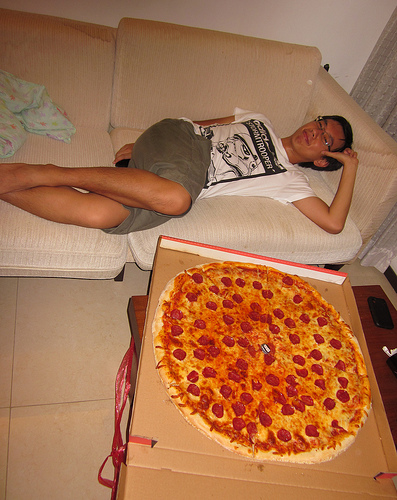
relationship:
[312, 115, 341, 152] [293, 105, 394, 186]
glasses on face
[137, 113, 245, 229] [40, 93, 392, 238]
shorts on man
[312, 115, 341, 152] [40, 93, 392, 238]
glasses on man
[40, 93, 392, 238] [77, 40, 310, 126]
man on couch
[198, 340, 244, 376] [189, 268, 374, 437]
pepperoni on pizza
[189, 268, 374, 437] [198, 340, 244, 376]
pizza on pepperoni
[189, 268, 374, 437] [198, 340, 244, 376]
pizza has pepperoni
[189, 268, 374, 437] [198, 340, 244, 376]
pizza with pepperoni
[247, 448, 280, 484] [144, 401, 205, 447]
stain on box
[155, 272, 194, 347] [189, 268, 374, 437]
crust on pizza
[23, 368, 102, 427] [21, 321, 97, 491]
lines on floor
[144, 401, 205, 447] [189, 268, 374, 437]
box with pizza